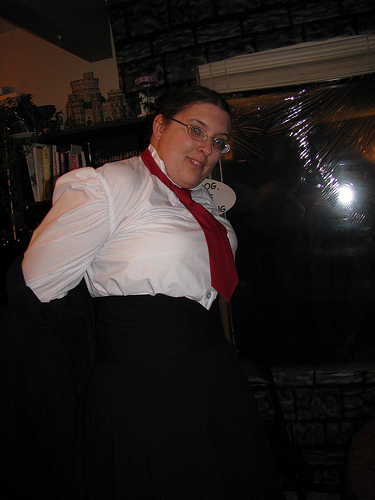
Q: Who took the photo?
A: Friend.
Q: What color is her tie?
A: Red.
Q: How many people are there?
A: 1.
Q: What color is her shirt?
A: White.